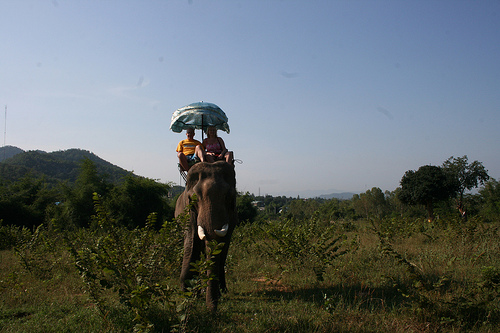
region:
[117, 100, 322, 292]
Couple riding an elephant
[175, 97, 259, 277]
two people riding an elephant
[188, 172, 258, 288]
an elephant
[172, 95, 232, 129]
a blue parasol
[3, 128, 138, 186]
green hills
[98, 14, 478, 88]
a stretch of blue clear sky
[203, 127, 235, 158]
woman wearing a pink tank top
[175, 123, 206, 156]
man wearing an orange shirt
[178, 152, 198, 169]
man wearing blue shorts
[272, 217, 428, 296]
small green bushes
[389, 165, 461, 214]
a green tree in full bloom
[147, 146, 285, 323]
A grey elephant stands in a grassy clearing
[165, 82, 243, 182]
Blue umbrella with a black pole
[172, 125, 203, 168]
Man in yellow shirt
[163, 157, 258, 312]
Elephant has large white tusks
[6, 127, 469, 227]
Hills behind the elephant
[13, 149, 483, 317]
Green, grassy clearing with shrubs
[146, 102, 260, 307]
Two people ride an elephant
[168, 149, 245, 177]
The people are sitting on a saddle strapped to the elephant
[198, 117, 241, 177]
A woman wearing pink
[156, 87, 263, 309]
The elephant is carrying two people under an umbrella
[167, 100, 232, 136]
A large, frilly blue parasol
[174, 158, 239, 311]
A grey elephant being ridden by two people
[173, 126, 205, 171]
A man riding an elephant beside a woman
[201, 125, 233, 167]
A woman riding an elephant beside a man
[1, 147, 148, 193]
A forested mountain in the background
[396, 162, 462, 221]
A solitary dark green leafy tree to the right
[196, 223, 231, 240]
The elephant's white, ivory tusks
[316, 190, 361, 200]
A barely-visible outline of a mountain in the distance on the right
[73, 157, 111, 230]
A tall pointed green tree in front of the mountains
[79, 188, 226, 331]
A sparse bush in front of the elephant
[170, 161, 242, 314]
The walking elephant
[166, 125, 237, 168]
The people riding on the elephant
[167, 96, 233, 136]
The umbrella over the people on the elephant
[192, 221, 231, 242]
The tusks of the elephant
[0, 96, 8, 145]
The tower on the mountain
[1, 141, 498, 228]
The mountain in the background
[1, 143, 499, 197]
The horizon line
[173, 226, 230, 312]
The legs of the elephant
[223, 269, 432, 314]
The shadow of the elephant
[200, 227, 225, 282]
The trunk of the elephant